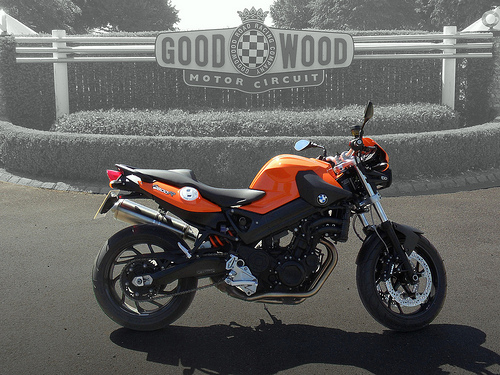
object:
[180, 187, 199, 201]
gas tank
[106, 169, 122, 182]
light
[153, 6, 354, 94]
sign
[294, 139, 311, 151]
mirror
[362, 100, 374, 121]
mirror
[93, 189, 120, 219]
license plate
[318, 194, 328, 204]
logo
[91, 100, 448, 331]
bike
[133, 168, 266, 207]
seat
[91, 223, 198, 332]
tires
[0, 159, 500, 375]
street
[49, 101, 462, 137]
bush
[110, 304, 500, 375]
shadow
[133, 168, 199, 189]
passenger seat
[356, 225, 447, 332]
wheel